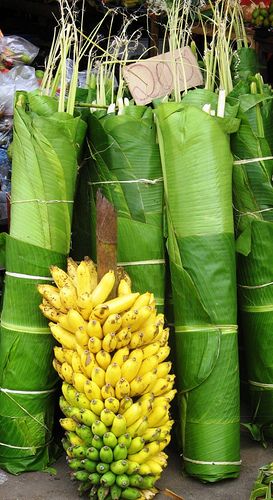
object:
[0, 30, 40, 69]
plastic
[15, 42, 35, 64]
lime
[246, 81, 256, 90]
stem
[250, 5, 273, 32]
lime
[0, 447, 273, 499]
floor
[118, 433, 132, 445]
abana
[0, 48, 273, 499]
banana leaf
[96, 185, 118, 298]
stem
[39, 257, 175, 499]
banana bunches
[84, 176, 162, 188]
string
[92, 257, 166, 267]
string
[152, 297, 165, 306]
string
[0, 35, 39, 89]
covers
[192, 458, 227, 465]
rope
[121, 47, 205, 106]
sign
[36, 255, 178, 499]
banana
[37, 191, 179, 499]
banana trunk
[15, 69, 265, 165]
large stalk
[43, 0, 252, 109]
shuts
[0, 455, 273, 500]
ground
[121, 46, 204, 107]
price card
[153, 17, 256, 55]
table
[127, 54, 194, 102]
writing